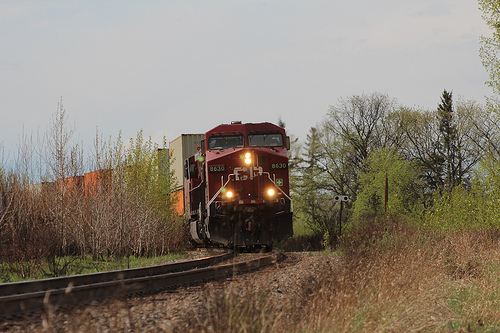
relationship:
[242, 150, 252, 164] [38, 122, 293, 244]
headlight on train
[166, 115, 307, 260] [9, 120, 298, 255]
train on train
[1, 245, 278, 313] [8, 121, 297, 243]
tracks holding train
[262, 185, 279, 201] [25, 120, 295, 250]
headlights are on train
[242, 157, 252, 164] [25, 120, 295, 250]
headlights are on train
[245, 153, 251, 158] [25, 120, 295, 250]
headlight are on train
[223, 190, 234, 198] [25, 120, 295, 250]
headlights are on train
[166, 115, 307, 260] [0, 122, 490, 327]
train on area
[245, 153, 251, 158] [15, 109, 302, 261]
headlight on engine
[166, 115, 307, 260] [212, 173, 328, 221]
train has lower headlights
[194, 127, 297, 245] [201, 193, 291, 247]
engine has guard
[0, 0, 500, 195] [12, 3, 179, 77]
clouds in sky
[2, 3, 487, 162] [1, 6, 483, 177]
clouds in sky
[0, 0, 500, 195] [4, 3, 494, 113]
clouds in sky